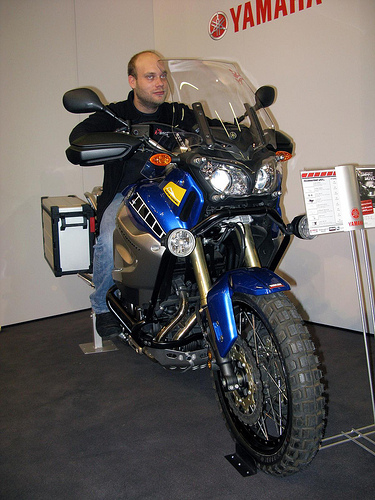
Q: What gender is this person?
A: Male.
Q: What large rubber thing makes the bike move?
A: Wheel.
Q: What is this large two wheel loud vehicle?
A: Motorcycle.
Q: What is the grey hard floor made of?
A: Concrete.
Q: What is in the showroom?
A: A bike.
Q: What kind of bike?
A: A motorcycle.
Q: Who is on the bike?
A: A man.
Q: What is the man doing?
A: Posing.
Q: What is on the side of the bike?
A: A wall.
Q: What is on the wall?
A: A sign.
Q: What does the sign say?
A: Yamaha.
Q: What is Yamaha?
A: The bike brand.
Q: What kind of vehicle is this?
A: Motorcycle.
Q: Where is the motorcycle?
A: Grey flooring.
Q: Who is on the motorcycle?
A: Man in black jacket.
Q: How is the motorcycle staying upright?
A: Black bolt plate on floor.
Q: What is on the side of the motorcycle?
A: White and black box.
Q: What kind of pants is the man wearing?
A: Blue jeans.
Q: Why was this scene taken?
A: For an ad.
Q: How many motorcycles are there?
A: One.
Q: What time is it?
A: Noon.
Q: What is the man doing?
A: Posing on the motorcycle.